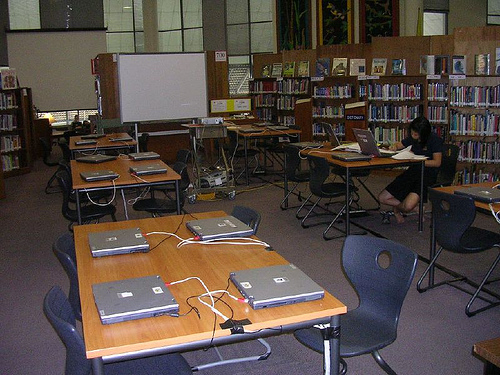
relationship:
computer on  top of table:
[85, 225, 151, 255] [67, 207, 352, 363]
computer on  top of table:
[86, 275, 180, 319] [67, 207, 352, 363]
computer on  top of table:
[186, 211, 253, 242] [67, 207, 352, 363]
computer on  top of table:
[130, 161, 165, 176] [61, 151, 188, 219]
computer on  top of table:
[223, 260, 326, 307] [67, 207, 352, 363]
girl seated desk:
[378, 116, 444, 223] [286, 135, 430, 242]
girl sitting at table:
[378, 116, 444, 223] [298, 145, 430, 240]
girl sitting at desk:
[378, 116, 444, 223] [299, 119, 435, 238]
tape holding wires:
[191, 364, 202, 373] [314, 322, 334, 373]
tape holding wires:
[256, 348, 272, 364] [167, 267, 246, 349]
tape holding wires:
[264, 242, 274, 252] [141, 222, 274, 249]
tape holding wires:
[314, 324, 343, 342] [84, 175, 150, 207]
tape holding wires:
[216, 315, 249, 335] [84, 175, 150, 207]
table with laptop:
[67, 207, 352, 363] [225, 260, 327, 313]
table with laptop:
[67, 207, 352, 363] [182, 212, 257, 243]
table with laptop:
[67, 207, 352, 363] [83, 224, 155, 261]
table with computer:
[67, 207, 352, 363] [90, 275, 180, 325]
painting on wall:
[274, 1, 316, 53] [273, 3, 414, 38]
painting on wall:
[316, 1, 356, 47] [273, 3, 414, 38]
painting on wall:
[355, 0, 405, 45] [273, 3, 414, 38]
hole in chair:
[378, 249, 392, 271] [298, 234, 416, 374]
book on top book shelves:
[452, 54, 463, 81] [247, 25, 500, 186]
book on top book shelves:
[473, 50, 488, 76] [247, 25, 500, 186]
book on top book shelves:
[493, 45, 499, 75] [247, 25, 500, 186]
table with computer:
[67, 207, 352, 363] [229, 259, 325, 313]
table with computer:
[67, 207, 352, 363] [189, 213, 253, 244]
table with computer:
[67, 207, 352, 363] [88, 225, 149, 259]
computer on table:
[186, 215, 253, 242] [67, 207, 352, 363]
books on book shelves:
[296, 57, 447, 158] [247, 25, 500, 186]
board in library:
[115, 50, 211, 125] [351, 30, 498, 206]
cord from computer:
[163, 275, 248, 318] [230, 264, 326, 309]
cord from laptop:
[164, 293, 282, 349] [91, 269, 180, 324]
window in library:
[103, 6, 148, 53] [2, 4, 479, 374]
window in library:
[154, 4, 201, 49] [2, 4, 479, 374]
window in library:
[226, 7, 273, 51] [2, 4, 479, 374]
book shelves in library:
[241, 25, 484, 197] [2, 4, 479, 374]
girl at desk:
[382, 123, 449, 195] [296, 139, 428, 233]